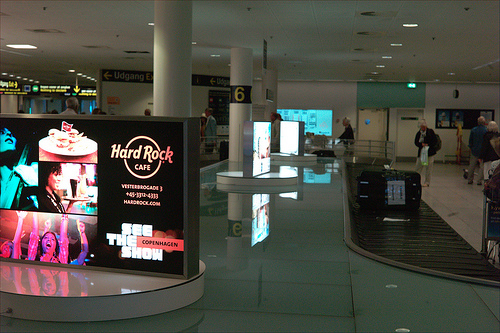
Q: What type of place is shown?
A: It is an airport.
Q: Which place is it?
A: It is an airport.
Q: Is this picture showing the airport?
A: Yes, it is showing the airport.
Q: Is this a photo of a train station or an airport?
A: It is showing an airport.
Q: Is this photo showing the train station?
A: No, the picture is showing the airport.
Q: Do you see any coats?
A: Yes, there is a coat.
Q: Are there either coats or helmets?
A: Yes, there is a coat.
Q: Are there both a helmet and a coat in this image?
A: No, there is a coat but no helmets.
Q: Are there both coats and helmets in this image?
A: No, there is a coat but no helmets.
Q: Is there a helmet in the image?
A: No, there are no helmets.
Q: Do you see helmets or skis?
A: No, there are no helmets or skis.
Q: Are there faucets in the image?
A: No, there are no faucets.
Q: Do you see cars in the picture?
A: No, there are no cars.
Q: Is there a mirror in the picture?
A: No, there are no mirrors.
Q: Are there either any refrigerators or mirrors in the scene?
A: No, there are no mirrors or refrigerators.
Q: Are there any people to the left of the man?
A: Yes, there is a person to the left of the man.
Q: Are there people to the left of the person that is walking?
A: Yes, there is a person to the left of the man.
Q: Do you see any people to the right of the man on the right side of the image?
A: No, the person is to the left of the man.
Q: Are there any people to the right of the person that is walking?
A: No, the person is to the left of the man.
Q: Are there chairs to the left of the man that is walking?
A: No, there is a person to the left of the man.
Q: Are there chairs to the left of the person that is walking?
A: No, there is a person to the left of the man.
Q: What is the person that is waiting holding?
A: The person is holding the bag.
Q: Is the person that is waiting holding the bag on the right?
A: Yes, the person is holding the bag.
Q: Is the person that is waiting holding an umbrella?
A: No, the person is holding the bag.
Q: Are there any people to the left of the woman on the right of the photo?
A: Yes, there is a person to the left of the woman.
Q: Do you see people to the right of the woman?
A: No, the person is to the left of the woman.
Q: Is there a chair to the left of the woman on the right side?
A: No, there is a person to the left of the woman.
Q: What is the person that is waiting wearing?
A: The person is wearing a coat.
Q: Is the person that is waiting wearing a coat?
A: Yes, the person is wearing a coat.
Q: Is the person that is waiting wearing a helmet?
A: No, the person is wearing a coat.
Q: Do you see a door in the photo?
A: Yes, there are doors.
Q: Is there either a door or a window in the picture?
A: Yes, there are doors.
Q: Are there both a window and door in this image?
A: No, there are doors but no windows.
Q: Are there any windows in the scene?
A: No, there are no windows.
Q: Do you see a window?
A: No, there are no windows.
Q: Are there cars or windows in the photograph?
A: No, there are no windows or cars.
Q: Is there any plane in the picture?
A: No, there are no airplanes.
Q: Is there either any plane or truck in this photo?
A: No, there are no airplanes or trucks.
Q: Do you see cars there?
A: No, there are no cars.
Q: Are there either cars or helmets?
A: No, there are no cars or helmets.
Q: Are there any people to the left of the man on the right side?
A: Yes, there is a person to the left of the man.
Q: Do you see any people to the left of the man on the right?
A: Yes, there is a person to the left of the man.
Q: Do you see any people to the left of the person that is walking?
A: Yes, there is a person to the left of the man.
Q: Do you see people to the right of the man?
A: No, the person is to the left of the man.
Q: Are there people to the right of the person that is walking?
A: No, the person is to the left of the man.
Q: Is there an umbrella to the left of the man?
A: No, there is a person to the left of the man.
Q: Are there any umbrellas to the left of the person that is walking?
A: No, there is a person to the left of the man.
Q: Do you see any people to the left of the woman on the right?
A: Yes, there is a person to the left of the woman.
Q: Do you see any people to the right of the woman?
A: No, the person is to the left of the woman.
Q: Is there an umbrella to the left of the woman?
A: No, there is a person to the left of the woman.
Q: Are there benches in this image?
A: No, there are no benches.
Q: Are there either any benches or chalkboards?
A: No, there are no benches or chalkboards.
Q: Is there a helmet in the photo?
A: No, there are no helmets.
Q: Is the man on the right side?
A: Yes, the man is on the right of the image.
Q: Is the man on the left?
A: No, the man is on the right of the image.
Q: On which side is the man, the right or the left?
A: The man is on the right of the image.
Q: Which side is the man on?
A: The man is on the right of the image.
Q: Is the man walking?
A: Yes, the man is walking.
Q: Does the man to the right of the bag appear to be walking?
A: Yes, the man is walking.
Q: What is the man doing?
A: The man is walking.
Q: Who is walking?
A: The man is walking.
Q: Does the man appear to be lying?
A: No, the man is walking.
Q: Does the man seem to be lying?
A: No, the man is walking.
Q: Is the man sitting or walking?
A: The man is walking.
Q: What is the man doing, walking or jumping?
A: The man is walking.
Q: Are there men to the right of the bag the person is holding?
A: Yes, there is a man to the right of the bag.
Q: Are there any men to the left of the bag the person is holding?
A: No, the man is to the right of the bag.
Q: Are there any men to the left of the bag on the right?
A: No, the man is to the right of the bag.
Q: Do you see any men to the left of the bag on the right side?
A: No, the man is to the right of the bag.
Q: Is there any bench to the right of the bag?
A: No, there is a man to the right of the bag.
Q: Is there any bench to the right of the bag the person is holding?
A: No, there is a man to the right of the bag.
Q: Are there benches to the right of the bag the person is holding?
A: No, there is a man to the right of the bag.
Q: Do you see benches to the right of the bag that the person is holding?
A: No, there is a man to the right of the bag.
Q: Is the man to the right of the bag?
A: Yes, the man is to the right of the bag.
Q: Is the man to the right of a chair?
A: No, the man is to the right of the bag.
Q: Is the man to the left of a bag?
A: No, the man is to the right of a bag.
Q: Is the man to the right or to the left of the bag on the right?
A: The man is to the right of the bag.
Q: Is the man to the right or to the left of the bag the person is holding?
A: The man is to the right of the bag.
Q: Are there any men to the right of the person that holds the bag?
A: Yes, there is a man to the right of the person.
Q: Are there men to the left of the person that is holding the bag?
A: No, the man is to the right of the person.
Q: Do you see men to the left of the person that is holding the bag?
A: No, the man is to the right of the person.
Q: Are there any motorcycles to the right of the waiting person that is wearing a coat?
A: No, there is a man to the right of the person.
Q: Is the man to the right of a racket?
A: No, the man is to the right of a person.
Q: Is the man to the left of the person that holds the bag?
A: No, the man is to the right of the person.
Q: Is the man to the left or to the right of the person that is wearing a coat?
A: The man is to the right of the person.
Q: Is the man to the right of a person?
A: Yes, the man is to the right of a person.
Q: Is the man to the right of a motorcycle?
A: No, the man is to the right of a person.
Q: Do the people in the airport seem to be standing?
A: Yes, the people are standing.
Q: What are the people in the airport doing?
A: The people are standing.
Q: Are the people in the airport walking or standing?
A: The people are standing.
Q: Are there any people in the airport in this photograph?
A: Yes, there are people in the airport.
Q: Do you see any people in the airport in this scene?
A: Yes, there are people in the airport.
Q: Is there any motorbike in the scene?
A: No, there are no motorcycles.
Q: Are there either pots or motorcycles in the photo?
A: No, there are no motorcycles or pots.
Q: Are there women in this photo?
A: Yes, there is a woman.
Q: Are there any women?
A: Yes, there is a woman.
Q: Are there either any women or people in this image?
A: Yes, there is a woman.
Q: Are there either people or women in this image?
A: Yes, there is a woman.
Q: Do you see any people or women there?
A: Yes, there is a woman.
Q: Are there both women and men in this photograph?
A: Yes, there are both a woman and a man.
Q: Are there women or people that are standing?
A: Yes, the woman is standing.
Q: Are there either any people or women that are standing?
A: Yes, the woman is standing.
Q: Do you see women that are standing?
A: Yes, there is a woman that is standing.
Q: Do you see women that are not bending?
A: Yes, there is a woman that is standing .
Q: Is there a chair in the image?
A: No, there are no chairs.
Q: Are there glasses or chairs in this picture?
A: No, there are no chairs or glasses.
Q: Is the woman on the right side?
A: Yes, the woman is on the right of the image.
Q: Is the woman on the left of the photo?
A: No, the woman is on the right of the image.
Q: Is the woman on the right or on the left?
A: The woman is on the right of the image.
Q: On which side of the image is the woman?
A: The woman is on the right of the image.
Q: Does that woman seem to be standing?
A: Yes, the woman is standing.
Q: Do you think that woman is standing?
A: Yes, the woman is standing.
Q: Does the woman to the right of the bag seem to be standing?
A: Yes, the woman is standing.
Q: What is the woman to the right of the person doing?
A: The woman is standing.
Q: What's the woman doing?
A: The woman is standing.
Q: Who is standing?
A: The woman is standing.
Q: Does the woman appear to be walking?
A: No, the woman is standing.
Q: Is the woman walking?
A: No, the woman is standing.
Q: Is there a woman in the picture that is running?
A: No, there is a woman but she is standing.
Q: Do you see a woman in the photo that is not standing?
A: No, there is a woman but she is standing.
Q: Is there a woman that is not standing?
A: No, there is a woman but she is standing.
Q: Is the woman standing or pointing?
A: The woman is standing.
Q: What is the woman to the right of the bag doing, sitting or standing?
A: The woman is standing.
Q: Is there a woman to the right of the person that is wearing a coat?
A: Yes, there is a woman to the right of the person.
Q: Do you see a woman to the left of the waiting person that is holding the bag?
A: No, the woman is to the right of the person.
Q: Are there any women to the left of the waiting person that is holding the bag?
A: No, the woman is to the right of the person.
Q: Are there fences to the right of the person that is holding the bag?
A: No, there is a woman to the right of the person.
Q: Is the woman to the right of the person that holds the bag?
A: Yes, the woman is to the right of the person.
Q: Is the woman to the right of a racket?
A: No, the woman is to the right of the person.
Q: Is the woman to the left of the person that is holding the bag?
A: No, the woman is to the right of the person.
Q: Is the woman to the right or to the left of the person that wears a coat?
A: The woman is to the right of the person.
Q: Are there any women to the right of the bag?
A: Yes, there is a woman to the right of the bag.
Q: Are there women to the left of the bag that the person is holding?
A: No, the woman is to the right of the bag.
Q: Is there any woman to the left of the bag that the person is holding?
A: No, the woman is to the right of the bag.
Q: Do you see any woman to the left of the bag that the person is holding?
A: No, the woman is to the right of the bag.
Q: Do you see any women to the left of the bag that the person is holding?
A: No, the woman is to the right of the bag.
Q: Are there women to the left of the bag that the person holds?
A: No, the woman is to the right of the bag.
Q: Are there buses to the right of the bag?
A: No, there is a woman to the right of the bag.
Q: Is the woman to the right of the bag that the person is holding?
A: Yes, the woman is to the right of the bag.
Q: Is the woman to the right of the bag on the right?
A: Yes, the woman is to the right of the bag.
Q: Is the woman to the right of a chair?
A: No, the woman is to the right of the bag.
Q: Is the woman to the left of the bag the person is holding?
A: No, the woman is to the right of the bag.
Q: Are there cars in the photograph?
A: No, there are no cars.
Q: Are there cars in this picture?
A: No, there are no cars.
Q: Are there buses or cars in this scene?
A: No, there are no cars or buses.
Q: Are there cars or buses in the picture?
A: No, there are no cars or buses.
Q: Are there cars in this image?
A: No, there are no cars.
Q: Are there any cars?
A: No, there are no cars.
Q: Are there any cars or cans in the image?
A: No, there are no cars or cans.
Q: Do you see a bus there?
A: No, there are no buses.